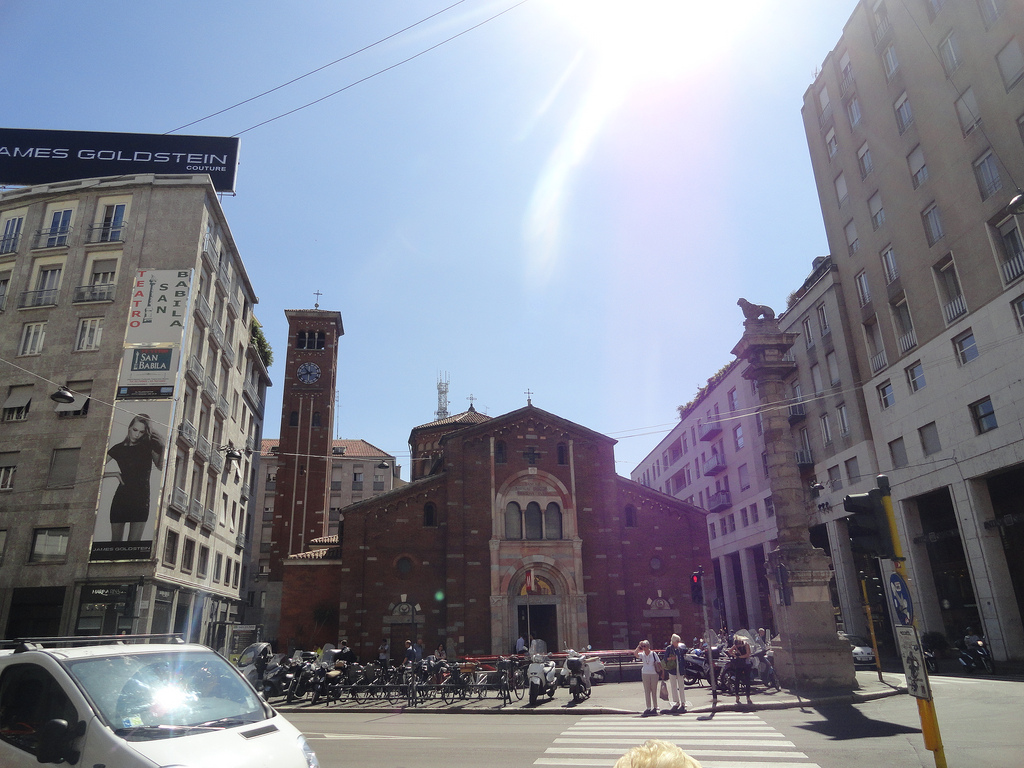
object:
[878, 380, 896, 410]
window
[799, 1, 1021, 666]
building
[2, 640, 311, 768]
white car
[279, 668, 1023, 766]
street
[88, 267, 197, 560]
advertisment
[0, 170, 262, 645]
building